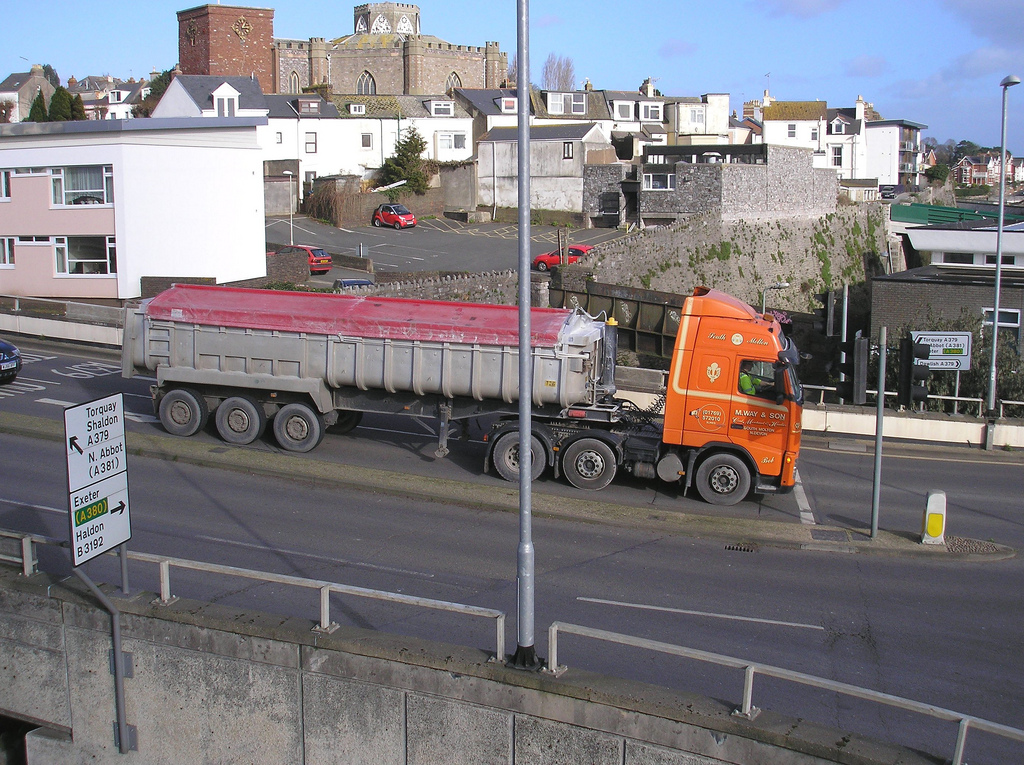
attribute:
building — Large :
[276, 2, 512, 102]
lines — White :
[574, 589, 827, 641]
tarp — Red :
[153, 276, 577, 343]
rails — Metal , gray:
[2, 528, 1023, 762]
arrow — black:
[63, 427, 89, 465]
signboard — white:
[45, 383, 138, 574]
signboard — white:
[35, 371, 222, 707]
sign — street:
[52, 407, 141, 563]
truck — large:
[111, 254, 820, 536]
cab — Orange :
[662, 283, 796, 496]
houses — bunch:
[3, 62, 939, 215]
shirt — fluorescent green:
[741, 371, 755, 395]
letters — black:
[82, 409, 121, 474]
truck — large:
[127, 282, 800, 511]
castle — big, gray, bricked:
[170, 7, 514, 100]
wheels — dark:
[153, 379, 759, 511]